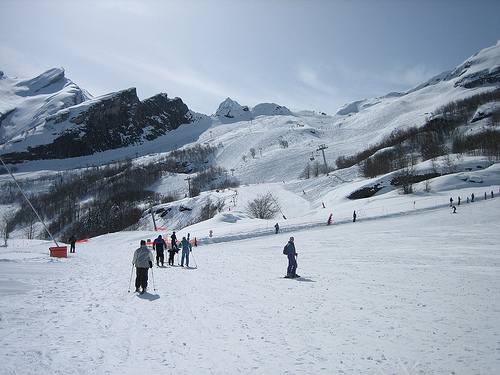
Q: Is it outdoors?
A: Yes, it is outdoors.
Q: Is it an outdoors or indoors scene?
A: It is outdoors.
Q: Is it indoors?
A: No, it is outdoors.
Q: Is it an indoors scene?
A: No, it is outdoors.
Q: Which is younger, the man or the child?
A: The child is younger than the man.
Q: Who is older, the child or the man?
A: The man is older than the child.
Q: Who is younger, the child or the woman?
A: The child is younger than the woman.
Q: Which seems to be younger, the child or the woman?
A: The child is younger than the woman.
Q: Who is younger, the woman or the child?
A: The child is younger than the woman.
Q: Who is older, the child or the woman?
A: The woman is older than the child.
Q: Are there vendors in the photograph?
A: No, there are no vendors.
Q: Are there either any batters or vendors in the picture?
A: No, there are no vendors or batters.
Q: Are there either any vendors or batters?
A: No, there are no vendors or batters.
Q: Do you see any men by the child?
A: Yes, there is a man by the child.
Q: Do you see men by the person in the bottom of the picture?
A: Yes, there is a man by the child.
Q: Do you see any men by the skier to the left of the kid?
A: Yes, there is a man by the skier.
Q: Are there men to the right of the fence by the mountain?
A: Yes, there is a man to the right of the fence.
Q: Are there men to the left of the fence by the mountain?
A: No, the man is to the right of the fence.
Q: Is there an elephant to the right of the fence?
A: No, there is a man to the right of the fence.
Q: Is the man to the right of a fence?
A: Yes, the man is to the right of a fence.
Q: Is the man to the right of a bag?
A: No, the man is to the right of a fence.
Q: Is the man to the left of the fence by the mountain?
A: No, the man is to the right of the fence.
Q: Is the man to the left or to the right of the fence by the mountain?
A: The man is to the right of the fence.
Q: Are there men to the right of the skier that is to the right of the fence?
A: Yes, there is a man to the right of the skier.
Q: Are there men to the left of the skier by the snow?
A: No, the man is to the right of the skier.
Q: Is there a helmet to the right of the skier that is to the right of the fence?
A: No, there is a man to the right of the skier.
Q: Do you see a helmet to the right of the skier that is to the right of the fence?
A: No, there is a man to the right of the skier.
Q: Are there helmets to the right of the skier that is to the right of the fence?
A: No, there is a man to the right of the skier.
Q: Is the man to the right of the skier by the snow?
A: Yes, the man is to the right of the skier.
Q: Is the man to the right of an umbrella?
A: No, the man is to the right of the skier.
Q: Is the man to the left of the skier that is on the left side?
A: No, the man is to the right of the skier.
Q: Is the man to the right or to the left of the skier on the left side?
A: The man is to the right of the skier.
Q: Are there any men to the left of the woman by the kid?
A: Yes, there is a man to the left of the woman.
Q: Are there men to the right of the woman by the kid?
A: No, the man is to the left of the woman.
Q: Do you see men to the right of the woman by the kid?
A: No, the man is to the left of the woman.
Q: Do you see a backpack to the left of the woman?
A: No, there is a man to the left of the woman.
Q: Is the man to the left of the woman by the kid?
A: Yes, the man is to the left of the woman.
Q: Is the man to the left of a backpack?
A: No, the man is to the left of the woman.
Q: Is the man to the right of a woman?
A: No, the man is to the left of a woman.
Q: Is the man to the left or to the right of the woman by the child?
A: The man is to the left of the woman.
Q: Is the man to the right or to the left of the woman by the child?
A: The man is to the left of the woman.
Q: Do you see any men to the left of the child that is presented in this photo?
A: Yes, there is a man to the left of the child.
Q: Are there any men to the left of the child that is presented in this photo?
A: Yes, there is a man to the left of the child.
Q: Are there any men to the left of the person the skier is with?
A: Yes, there is a man to the left of the child.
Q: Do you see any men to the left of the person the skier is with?
A: Yes, there is a man to the left of the child.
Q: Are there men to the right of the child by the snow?
A: No, the man is to the left of the kid.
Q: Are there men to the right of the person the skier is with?
A: No, the man is to the left of the kid.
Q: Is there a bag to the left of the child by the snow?
A: No, there is a man to the left of the child.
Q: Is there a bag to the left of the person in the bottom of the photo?
A: No, there is a man to the left of the child.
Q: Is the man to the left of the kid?
A: Yes, the man is to the left of the kid.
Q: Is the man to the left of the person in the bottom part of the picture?
A: Yes, the man is to the left of the kid.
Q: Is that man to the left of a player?
A: No, the man is to the left of the kid.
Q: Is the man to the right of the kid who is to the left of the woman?
A: No, the man is to the left of the kid.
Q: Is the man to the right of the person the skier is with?
A: No, the man is to the left of the kid.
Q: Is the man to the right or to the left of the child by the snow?
A: The man is to the left of the kid.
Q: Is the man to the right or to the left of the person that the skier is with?
A: The man is to the left of the kid.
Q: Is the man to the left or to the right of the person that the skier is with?
A: The man is to the left of the kid.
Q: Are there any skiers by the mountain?
A: Yes, there is a skier by the mountain.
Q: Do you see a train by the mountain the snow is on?
A: No, there is a skier by the mountain.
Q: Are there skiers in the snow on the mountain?
A: Yes, there is a skier in the snow.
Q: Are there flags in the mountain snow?
A: No, there is a skier in the snow.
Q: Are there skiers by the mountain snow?
A: Yes, there is a skier by the snow.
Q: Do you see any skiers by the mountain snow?
A: Yes, there is a skier by the snow.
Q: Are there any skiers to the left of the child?
A: Yes, there is a skier to the left of the child.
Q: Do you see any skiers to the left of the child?
A: Yes, there is a skier to the left of the child.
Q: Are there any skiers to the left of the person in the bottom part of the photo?
A: Yes, there is a skier to the left of the child.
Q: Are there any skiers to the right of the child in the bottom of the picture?
A: No, the skier is to the left of the child.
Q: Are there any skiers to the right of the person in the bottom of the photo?
A: No, the skier is to the left of the child.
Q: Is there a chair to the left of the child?
A: No, there is a skier to the left of the child.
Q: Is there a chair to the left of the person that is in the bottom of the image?
A: No, there is a skier to the left of the child.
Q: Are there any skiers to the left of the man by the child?
A: Yes, there is a skier to the left of the man.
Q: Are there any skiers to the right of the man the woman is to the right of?
A: No, the skier is to the left of the man.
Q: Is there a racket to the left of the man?
A: No, there is a skier to the left of the man.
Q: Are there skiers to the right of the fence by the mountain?
A: Yes, there is a skier to the right of the fence.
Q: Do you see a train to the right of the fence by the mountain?
A: No, there is a skier to the right of the fence.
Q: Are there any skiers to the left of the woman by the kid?
A: Yes, there is a skier to the left of the woman.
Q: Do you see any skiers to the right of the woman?
A: No, the skier is to the left of the woman.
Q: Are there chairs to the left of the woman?
A: No, there is a skier to the left of the woman.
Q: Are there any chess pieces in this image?
A: No, there are no chess pieces.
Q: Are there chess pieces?
A: No, there are no chess pieces.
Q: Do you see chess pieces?
A: No, there are no chess pieces.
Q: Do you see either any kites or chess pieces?
A: No, there are no chess pieces or kites.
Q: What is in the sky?
A: The clouds are in the sky.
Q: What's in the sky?
A: The clouds are in the sky.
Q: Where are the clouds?
A: The clouds are in the sky.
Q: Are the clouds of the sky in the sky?
A: Yes, the clouds are in the sky.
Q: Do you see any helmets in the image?
A: No, there are no helmets.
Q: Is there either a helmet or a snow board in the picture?
A: No, there are no helmets or snowboards.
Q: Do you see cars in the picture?
A: No, there are no cars.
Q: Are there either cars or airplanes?
A: No, there are no cars or airplanes.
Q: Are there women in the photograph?
A: Yes, there is a woman.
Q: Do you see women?
A: Yes, there is a woman.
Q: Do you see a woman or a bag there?
A: Yes, there is a woman.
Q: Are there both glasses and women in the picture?
A: No, there is a woman but no glasses.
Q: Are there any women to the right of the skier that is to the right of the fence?
A: Yes, there is a woman to the right of the skier.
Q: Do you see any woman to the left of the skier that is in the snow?
A: No, the woman is to the right of the skier.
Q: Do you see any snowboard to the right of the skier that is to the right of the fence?
A: No, there is a woman to the right of the skier.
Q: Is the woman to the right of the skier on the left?
A: Yes, the woman is to the right of the skier.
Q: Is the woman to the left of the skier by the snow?
A: No, the woman is to the right of the skier.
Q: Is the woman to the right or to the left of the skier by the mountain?
A: The woman is to the right of the skier.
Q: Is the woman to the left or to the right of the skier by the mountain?
A: The woman is to the right of the skier.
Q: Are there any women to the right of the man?
A: Yes, there is a woman to the right of the man.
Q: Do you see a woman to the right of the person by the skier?
A: Yes, there is a woman to the right of the man.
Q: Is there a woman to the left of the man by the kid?
A: No, the woman is to the right of the man.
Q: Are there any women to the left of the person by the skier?
A: No, the woman is to the right of the man.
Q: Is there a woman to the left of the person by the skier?
A: No, the woman is to the right of the man.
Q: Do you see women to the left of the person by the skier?
A: No, the woman is to the right of the man.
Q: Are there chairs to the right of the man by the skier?
A: No, there is a woman to the right of the man.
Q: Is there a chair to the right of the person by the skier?
A: No, there is a woman to the right of the man.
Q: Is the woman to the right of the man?
A: Yes, the woman is to the right of the man.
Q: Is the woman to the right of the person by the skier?
A: Yes, the woman is to the right of the man.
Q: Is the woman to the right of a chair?
A: No, the woman is to the right of the man.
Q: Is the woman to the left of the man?
A: No, the woman is to the right of the man.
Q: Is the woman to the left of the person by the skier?
A: No, the woman is to the right of the man.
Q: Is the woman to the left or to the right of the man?
A: The woman is to the right of the man.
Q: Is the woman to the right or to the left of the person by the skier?
A: The woman is to the right of the man.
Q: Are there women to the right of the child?
A: Yes, there is a woman to the right of the child.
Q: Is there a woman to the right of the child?
A: Yes, there is a woman to the right of the child.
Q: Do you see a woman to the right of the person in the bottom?
A: Yes, there is a woman to the right of the child.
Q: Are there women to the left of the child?
A: No, the woman is to the right of the child.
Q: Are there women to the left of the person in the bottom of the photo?
A: No, the woman is to the right of the child.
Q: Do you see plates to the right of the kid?
A: No, there is a woman to the right of the kid.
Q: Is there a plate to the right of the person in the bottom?
A: No, there is a woman to the right of the kid.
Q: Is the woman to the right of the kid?
A: Yes, the woman is to the right of the kid.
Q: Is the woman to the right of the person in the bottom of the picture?
A: Yes, the woman is to the right of the kid.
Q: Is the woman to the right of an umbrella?
A: No, the woman is to the right of the kid.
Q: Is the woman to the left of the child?
A: No, the woman is to the right of the child.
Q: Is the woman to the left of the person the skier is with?
A: No, the woman is to the right of the child.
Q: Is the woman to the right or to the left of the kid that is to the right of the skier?
A: The woman is to the right of the kid.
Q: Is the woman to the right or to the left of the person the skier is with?
A: The woman is to the right of the kid.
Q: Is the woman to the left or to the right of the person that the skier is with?
A: The woman is to the right of the kid.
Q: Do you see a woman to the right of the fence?
A: Yes, there is a woman to the right of the fence.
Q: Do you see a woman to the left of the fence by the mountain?
A: No, the woman is to the right of the fence.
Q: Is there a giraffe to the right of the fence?
A: No, there is a woman to the right of the fence.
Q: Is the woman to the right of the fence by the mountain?
A: Yes, the woman is to the right of the fence.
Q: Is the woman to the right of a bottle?
A: No, the woman is to the right of the fence.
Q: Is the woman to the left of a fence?
A: No, the woman is to the right of a fence.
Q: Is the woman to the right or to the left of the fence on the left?
A: The woman is to the right of the fence.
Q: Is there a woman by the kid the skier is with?
A: Yes, there is a woman by the kid.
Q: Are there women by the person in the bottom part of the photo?
A: Yes, there is a woman by the kid.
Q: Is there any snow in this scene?
A: Yes, there is snow.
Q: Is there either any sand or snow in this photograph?
A: Yes, there is snow.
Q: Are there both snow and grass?
A: No, there is snow but no grass.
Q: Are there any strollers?
A: No, there are no strollers.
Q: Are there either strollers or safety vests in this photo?
A: No, there are no strollers or safety vests.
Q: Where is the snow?
A: The snow is on the mountain.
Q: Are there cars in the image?
A: No, there are no cars.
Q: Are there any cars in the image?
A: No, there are no cars.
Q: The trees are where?
A: The trees are in the snow.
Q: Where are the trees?
A: The trees are in the snow.